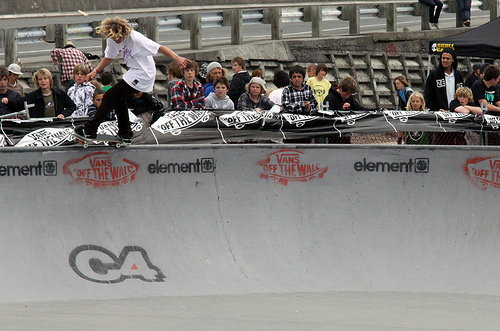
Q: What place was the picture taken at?
A: It was taken at the skate park.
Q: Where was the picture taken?
A: It was taken at the skate park.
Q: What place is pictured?
A: It is a skate park.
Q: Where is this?
A: This is at the skate park.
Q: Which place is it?
A: It is a skate park.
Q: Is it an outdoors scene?
A: Yes, it is outdoors.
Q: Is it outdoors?
A: Yes, it is outdoors.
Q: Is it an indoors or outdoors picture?
A: It is outdoors.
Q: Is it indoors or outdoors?
A: It is outdoors.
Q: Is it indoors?
A: No, it is outdoors.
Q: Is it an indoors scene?
A: No, it is outdoors.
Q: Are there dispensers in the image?
A: No, there are no dispensers.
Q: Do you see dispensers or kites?
A: No, there are no dispensers or kites.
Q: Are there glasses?
A: No, there are no glasses.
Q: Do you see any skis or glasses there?
A: No, there are no glasses or skis.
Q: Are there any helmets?
A: No, there are no helmets.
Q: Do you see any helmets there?
A: No, there are no helmets.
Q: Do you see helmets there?
A: No, there are no helmets.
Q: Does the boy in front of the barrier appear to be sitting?
A: Yes, the boy is sitting.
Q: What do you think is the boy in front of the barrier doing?
A: The boy is sitting.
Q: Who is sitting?
A: The boy is sitting.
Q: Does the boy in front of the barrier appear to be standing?
A: No, the boy is sitting.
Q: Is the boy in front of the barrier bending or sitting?
A: The boy is sitting.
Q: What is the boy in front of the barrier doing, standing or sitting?
A: The boy is sitting.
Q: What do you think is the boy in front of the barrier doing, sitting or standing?
A: The boy is sitting.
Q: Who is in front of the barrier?
A: The boy is in front of the barrier.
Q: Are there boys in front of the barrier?
A: Yes, there is a boy in front of the barrier.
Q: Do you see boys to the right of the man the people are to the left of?
A: Yes, there is a boy to the right of the man.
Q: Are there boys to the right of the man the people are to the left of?
A: Yes, there is a boy to the right of the man.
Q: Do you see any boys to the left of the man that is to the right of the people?
A: No, the boy is to the right of the man.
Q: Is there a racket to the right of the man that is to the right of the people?
A: No, there is a boy to the right of the man.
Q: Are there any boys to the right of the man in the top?
A: Yes, there is a boy to the right of the man.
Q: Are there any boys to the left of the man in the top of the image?
A: No, the boy is to the right of the man.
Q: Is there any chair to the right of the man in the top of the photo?
A: No, there is a boy to the right of the man.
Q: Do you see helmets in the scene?
A: No, there are no helmets.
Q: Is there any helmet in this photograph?
A: No, there are no helmets.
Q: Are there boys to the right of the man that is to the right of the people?
A: Yes, there is a boy to the right of the man.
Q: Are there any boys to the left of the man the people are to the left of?
A: No, the boy is to the right of the man.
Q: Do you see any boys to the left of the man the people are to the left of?
A: No, the boy is to the right of the man.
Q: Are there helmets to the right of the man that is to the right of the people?
A: No, there is a boy to the right of the man.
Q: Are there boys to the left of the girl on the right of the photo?
A: Yes, there is a boy to the left of the girl.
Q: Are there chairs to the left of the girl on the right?
A: No, there is a boy to the left of the girl.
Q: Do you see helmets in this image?
A: No, there are no helmets.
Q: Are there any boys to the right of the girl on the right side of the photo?
A: Yes, there is a boy to the right of the girl.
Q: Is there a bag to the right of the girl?
A: No, there is a boy to the right of the girl.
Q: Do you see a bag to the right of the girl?
A: No, there is a boy to the right of the girl.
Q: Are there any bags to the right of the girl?
A: No, there is a boy to the right of the girl.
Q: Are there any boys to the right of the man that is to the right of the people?
A: Yes, there is a boy to the right of the man.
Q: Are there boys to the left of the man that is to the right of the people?
A: No, the boy is to the right of the man.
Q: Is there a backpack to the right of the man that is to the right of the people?
A: No, there is a boy to the right of the man.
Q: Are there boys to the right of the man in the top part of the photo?
A: Yes, there is a boy to the right of the man.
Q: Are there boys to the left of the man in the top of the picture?
A: No, the boy is to the right of the man.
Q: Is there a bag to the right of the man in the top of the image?
A: No, there is a boy to the right of the man.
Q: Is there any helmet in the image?
A: No, there are no helmets.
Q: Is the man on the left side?
A: Yes, the man is on the left of the image.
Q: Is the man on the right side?
A: No, the man is on the left of the image.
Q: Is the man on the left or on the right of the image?
A: The man is on the left of the image.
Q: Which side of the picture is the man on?
A: The man is on the left of the image.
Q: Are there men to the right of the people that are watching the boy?
A: Yes, there is a man to the right of the people.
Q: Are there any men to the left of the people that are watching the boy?
A: No, the man is to the right of the people.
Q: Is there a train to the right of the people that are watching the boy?
A: No, there is a man to the right of the people.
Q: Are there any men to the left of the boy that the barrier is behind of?
A: Yes, there is a man to the left of the boy.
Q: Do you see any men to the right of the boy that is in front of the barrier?
A: No, the man is to the left of the boy.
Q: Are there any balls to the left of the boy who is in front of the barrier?
A: No, there is a man to the left of the boy.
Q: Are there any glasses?
A: No, there are no glasses.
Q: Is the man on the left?
A: Yes, the man is on the left of the image.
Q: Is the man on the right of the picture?
A: No, the man is on the left of the image.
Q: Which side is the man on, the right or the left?
A: The man is on the left of the image.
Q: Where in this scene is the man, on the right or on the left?
A: The man is on the left of the image.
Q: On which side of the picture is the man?
A: The man is on the left of the image.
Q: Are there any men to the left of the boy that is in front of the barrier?
A: Yes, there is a man to the left of the boy.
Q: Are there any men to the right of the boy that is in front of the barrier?
A: No, the man is to the left of the boy.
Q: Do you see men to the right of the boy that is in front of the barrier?
A: No, the man is to the left of the boy.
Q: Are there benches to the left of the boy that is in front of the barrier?
A: No, there is a man to the left of the boy.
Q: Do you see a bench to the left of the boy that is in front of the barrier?
A: No, there is a man to the left of the boy.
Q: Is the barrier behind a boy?
A: Yes, the barrier is behind a boy.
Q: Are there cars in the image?
A: No, there are no cars.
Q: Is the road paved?
A: Yes, the road is paved.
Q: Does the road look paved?
A: Yes, the road is paved.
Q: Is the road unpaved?
A: No, the road is paved.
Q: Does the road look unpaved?
A: No, the road is paved.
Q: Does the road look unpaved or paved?
A: The road is paved.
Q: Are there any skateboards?
A: Yes, there is a skateboard.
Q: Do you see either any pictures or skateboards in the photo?
A: Yes, there is a skateboard.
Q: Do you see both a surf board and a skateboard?
A: No, there is a skateboard but no surfboards.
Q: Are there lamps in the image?
A: No, there are no lamps.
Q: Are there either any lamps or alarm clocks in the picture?
A: No, there are no lamps or alarm clocks.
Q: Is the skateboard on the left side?
A: Yes, the skateboard is on the left of the image.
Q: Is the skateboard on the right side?
A: No, the skateboard is on the left of the image.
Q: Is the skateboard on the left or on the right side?
A: The skateboard is on the left of the image.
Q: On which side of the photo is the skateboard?
A: The skateboard is on the left of the image.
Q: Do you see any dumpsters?
A: No, there are no dumpsters.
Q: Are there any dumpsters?
A: No, there are no dumpsters.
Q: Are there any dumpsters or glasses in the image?
A: No, there are no dumpsters or glasses.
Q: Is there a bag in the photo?
A: No, there are no bags.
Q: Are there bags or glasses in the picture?
A: No, there are no bags or glasses.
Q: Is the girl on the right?
A: Yes, the girl is on the right of the image.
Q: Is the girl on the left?
A: No, the girl is on the right of the image.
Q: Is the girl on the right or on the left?
A: The girl is on the right of the image.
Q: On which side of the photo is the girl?
A: The girl is on the right of the image.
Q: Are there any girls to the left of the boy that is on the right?
A: Yes, there is a girl to the left of the boy.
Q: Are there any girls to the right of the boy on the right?
A: No, the girl is to the left of the boy.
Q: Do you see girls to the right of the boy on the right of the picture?
A: No, the girl is to the left of the boy.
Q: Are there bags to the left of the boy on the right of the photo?
A: No, there is a girl to the left of the boy.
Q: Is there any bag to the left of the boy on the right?
A: No, there is a girl to the left of the boy.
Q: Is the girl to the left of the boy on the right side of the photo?
A: Yes, the girl is to the left of the boy.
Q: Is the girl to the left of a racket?
A: No, the girl is to the left of the boy.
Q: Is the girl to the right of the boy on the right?
A: No, the girl is to the left of the boy.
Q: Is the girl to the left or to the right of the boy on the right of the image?
A: The girl is to the left of the boy.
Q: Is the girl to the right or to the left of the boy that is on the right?
A: The girl is to the left of the boy.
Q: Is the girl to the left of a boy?
A: No, the girl is to the right of a boy.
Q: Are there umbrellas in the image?
A: No, there are no umbrellas.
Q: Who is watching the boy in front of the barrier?
A: The people are watching the boy.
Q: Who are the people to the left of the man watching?
A: The people are watching the boy.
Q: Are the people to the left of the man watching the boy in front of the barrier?
A: Yes, the people are watching the boy.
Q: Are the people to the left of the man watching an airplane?
A: No, the people are watching the boy.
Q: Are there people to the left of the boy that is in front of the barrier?
A: Yes, there are people to the left of the boy.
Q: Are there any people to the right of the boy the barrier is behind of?
A: No, the people are to the left of the boy.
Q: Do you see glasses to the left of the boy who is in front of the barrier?
A: No, there are people to the left of the boy.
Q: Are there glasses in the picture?
A: No, there are no glasses.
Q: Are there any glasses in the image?
A: No, there are no glasses.